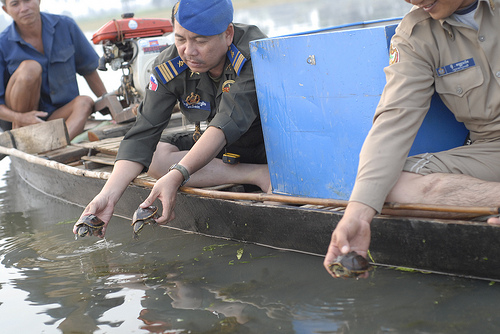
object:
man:
[70, 0, 286, 243]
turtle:
[71, 213, 107, 240]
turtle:
[126, 205, 160, 239]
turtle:
[320, 251, 374, 282]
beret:
[170, 1, 236, 36]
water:
[0, 144, 500, 334]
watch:
[166, 161, 191, 184]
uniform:
[113, 21, 274, 169]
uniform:
[343, 0, 500, 218]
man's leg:
[389, 170, 499, 220]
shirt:
[0, 7, 103, 122]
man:
[0, 0, 110, 144]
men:
[322, 1, 499, 282]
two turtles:
[73, 202, 165, 240]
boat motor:
[92, 11, 187, 115]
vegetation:
[224, 241, 257, 263]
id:
[435, 55, 478, 79]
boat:
[0, 6, 497, 283]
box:
[248, 13, 469, 201]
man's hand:
[70, 194, 114, 245]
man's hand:
[136, 171, 181, 228]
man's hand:
[320, 216, 375, 282]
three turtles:
[67, 204, 374, 282]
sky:
[0, 0, 417, 121]